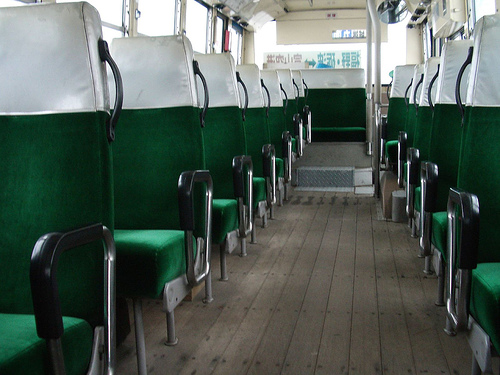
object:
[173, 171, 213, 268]
arms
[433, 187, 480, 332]
arms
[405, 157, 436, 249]
arms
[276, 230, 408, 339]
floor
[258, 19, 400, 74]
windshield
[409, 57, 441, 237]
seat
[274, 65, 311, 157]
seat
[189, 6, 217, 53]
window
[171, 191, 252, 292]
rest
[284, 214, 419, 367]
hardwood floors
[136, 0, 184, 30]
window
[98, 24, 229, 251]
white seat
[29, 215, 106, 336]
arm rest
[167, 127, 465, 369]
aisle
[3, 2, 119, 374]
seating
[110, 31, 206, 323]
seating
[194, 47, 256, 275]
seating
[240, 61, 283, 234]
seating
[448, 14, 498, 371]
seating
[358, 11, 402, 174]
pole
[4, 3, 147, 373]
seat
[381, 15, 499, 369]
bus seats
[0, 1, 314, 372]
bus seats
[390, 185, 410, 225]
canister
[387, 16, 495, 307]
seat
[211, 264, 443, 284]
line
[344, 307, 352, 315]
nail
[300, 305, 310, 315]
nail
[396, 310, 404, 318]
nail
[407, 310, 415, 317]
nail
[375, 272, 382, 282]
nail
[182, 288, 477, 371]
floor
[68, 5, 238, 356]
seat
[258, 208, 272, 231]
pole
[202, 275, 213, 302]
pole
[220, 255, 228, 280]
pole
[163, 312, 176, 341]
pole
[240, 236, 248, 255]
pole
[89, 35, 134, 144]
handle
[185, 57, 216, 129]
handle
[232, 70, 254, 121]
handle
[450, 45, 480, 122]
handle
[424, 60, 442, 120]
handle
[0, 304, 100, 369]
seat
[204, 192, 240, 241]
seat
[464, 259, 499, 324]
seat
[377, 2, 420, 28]
mirror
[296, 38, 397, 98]
glass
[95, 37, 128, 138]
skier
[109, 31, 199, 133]
back seat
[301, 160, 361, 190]
grate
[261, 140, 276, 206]
arm rest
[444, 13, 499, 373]
chair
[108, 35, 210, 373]
chair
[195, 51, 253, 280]
chair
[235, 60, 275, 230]
chair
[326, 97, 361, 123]
seat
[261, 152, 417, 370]
floor plank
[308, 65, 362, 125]
back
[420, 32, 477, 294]
seat